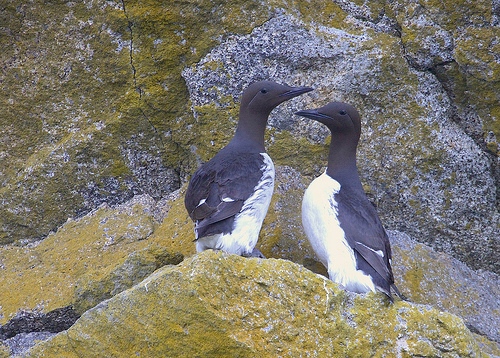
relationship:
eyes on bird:
[262, 87, 269, 95] [182, 81, 315, 257]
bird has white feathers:
[288, 102, 393, 307] [303, 164, 384, 290]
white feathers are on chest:
[303, 164, 384, 290] [296, 177, 338, 241]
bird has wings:
[288, 102, 393, 307] [338, 189, 401, 295]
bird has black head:
[182, 81, 315, 257] [233, 72, 316, 142]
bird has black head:
[288, 102, 393, 307] [293, 95, 365, 170]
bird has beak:
[288, 102, 393, 307] [294, 104, 325, 121]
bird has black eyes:
[182, 81, 315, 257] [338, 108, 347, 115]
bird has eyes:
[288, 102, 393, 307] [262, 87, 269, 95]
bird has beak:
[182, 81, 315, 257] [285, 85, 310, 92]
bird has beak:
[182, 81, 315, 257] [293, 106, 326, 124]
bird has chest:
[284, 93, 414, 308] [306, 182, 336, 257]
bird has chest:
[182, 81, 315, 257] [235, 147, 274, 253]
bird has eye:
[182, 81, 315, 257] [261, 88, 267, 95]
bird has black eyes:
[288, 102, 393, 307] [338, 108, 347, 115]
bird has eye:
[288, 102, 393, 307] [335, 106, 347, 116]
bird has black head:
[288, 102, 393, 307] [293, 99, 361, 136]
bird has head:
[288, 102, 393, 307] [296, 103, 362, 133]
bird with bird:
[288, 102, 393, 307] [186, 77, 314, 257]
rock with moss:
[1, 2, 498, 354] [95, 0, 221, 175]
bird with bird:
[182, 81, 315, 257] [296, 74, 409, 291]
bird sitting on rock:
[198, 47, 263, 264] [40, 248, 498, 356]